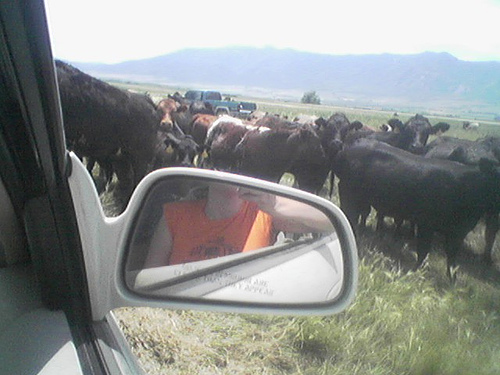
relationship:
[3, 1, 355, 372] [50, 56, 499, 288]
car near cattle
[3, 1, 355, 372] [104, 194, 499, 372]
car in next to grass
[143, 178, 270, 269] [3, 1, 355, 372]
person in a car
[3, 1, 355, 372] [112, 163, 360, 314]
car has a mirror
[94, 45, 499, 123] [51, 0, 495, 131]
mountain in background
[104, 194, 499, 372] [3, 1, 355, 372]
grass beside a car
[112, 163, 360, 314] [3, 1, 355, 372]
mirror on a car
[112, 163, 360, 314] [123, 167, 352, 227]
mirror has a top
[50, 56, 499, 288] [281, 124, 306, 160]
cattle has a head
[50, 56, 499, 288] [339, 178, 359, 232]
cattle has a leg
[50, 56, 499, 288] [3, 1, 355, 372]
cattle outside car